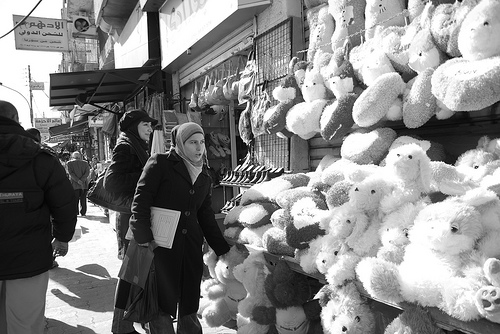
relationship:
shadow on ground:
[49, 252, 129, 315] [42, 218, 126, 331]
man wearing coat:
[0, 100, 78, 333] [1, 121, 76, 276]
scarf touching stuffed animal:
[168, 121, 215, 166] [191, 240, 247, 328]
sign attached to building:
[11, 16, 88, 51] [59, 0, 336, 220]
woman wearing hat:
[110, 103, 160, 160] [119, 106, 152, 124]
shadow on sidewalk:
[49, 252, 129, 315] [40, 212, 113, 326]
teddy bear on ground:
[312, 290, 381, 331] [24, 178, 240, 332]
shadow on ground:
[49, 252, 129, 315] [50, 211, 117, 331]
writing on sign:
[17, 16, 67, 49] [13, 4, 76, 55]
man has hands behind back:
[0, 101, 86, 332] [100, 186, 112, 283]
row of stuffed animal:
[257, 0, 499, 141] [286, 53, 333, 138]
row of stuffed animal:
[257, 0, 499, 141] [356, 184, 494, 320]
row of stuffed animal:
[257, 0, 499, 141] [324, 170, 405, 285]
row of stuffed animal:
[257, 0, 499, 141] [390, 25, 445, 125]